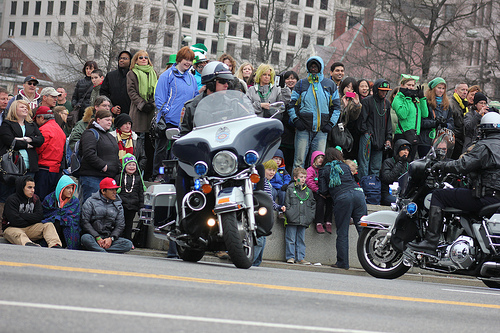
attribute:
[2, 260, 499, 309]
line — yellow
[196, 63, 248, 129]
officer — police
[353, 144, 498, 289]
motorbike — motor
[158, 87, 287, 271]
motorbike — motor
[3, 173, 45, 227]
sweatshirt — black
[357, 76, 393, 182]
man — young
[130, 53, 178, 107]
scarf — green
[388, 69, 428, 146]
girl — young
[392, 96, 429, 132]
jacket — blue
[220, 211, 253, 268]
tire — black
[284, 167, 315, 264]
boy — young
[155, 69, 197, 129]
coat — blue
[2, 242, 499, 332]
pavement — dark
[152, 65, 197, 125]
jacket — blue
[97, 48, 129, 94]
black coat — hooded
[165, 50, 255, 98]
scarf — blue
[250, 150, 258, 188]
headlights — motorcycle, on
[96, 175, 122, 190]
cap — red, baseball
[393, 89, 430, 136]
coat — green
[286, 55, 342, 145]
coat — blue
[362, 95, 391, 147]
sweatshirt — black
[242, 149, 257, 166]
light — blue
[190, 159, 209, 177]
light — blue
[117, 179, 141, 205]
necklace — shamrock 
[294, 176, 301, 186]
paint — green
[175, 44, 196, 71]
head — red